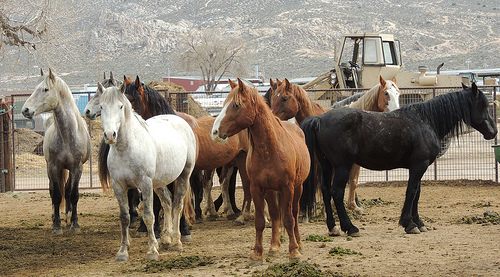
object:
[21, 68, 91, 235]
horse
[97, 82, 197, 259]
white horse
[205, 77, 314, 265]
brown horse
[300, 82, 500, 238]
black horse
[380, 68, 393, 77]
gray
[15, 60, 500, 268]
heard of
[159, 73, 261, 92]
red and gray barn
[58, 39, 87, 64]
distance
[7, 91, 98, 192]
metal gate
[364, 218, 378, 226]
dirt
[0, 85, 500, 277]
corral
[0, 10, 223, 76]
mountain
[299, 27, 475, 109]
bulldozer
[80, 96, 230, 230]
white horse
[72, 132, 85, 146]
grey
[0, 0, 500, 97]
background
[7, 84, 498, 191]
large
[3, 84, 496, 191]
fence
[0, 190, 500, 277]
large area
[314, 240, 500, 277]
patches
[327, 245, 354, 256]
green horse poop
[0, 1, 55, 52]
tree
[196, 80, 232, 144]
white stripe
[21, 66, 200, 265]
three horses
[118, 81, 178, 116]
black mane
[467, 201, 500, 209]
horse poop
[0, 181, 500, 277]
ground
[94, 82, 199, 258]
horse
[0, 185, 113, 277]
pasture